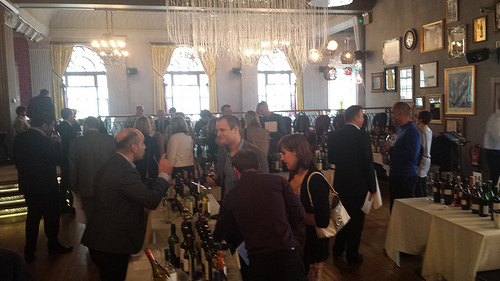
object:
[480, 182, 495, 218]
bottle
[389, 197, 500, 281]
table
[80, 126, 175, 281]
man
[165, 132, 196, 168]
jacket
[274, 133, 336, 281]
woman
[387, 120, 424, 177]
shirt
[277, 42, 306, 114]
drapes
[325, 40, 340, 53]
light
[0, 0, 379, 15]
ceiling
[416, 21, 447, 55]
picture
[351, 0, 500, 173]
wall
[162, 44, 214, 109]
window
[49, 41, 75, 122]
curtain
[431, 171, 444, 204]
wine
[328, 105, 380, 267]
people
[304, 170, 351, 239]
bag